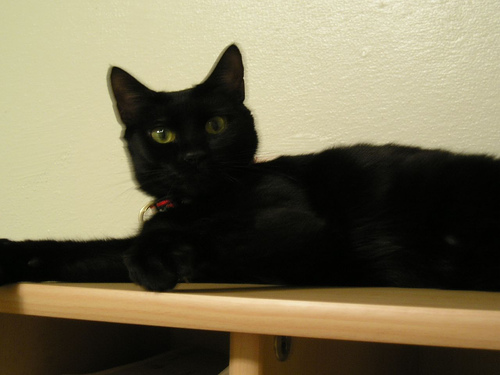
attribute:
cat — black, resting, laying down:
[1, 44, 498, 295]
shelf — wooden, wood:
[0, 277, 499, 352]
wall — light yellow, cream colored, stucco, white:
[1, 1, 498, 241]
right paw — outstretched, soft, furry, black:
[1, 237, 138, 283]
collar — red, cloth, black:
[150, 197, 195, 209]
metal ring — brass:
[140, 202, 158, 223]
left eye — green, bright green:
[204, 116, 227, 136]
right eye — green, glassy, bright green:
[149, 127, 176, 143]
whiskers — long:
[98, 171, 181, 198]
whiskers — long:
[207, 145, 286, 163]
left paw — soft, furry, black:
[122, 213, 182, 293]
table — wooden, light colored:
[1, 279, 500, 372]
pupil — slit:
[160, 132, 169, 142]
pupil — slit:
[212, 118, 219, 131]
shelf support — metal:
[274, 335, 294, 363]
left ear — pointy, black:
[203, 43, 246, 104]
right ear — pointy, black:
[107, 65, 156, 128]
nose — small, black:
[178, 151, 207, 166]